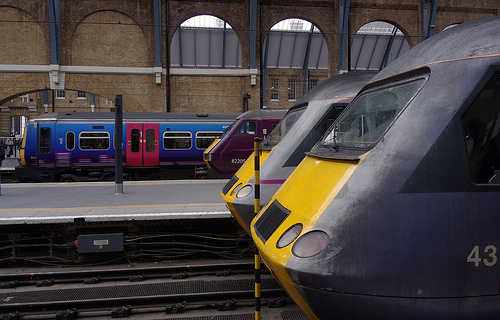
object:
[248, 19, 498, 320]
engine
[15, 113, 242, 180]
car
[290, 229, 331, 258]
light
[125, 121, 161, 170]
door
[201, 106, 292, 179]
train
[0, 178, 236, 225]
platform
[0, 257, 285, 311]
track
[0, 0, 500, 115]
wall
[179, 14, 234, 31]
window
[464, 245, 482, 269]
number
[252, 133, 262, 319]
pole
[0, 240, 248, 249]
cable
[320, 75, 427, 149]
windshield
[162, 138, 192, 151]
glass